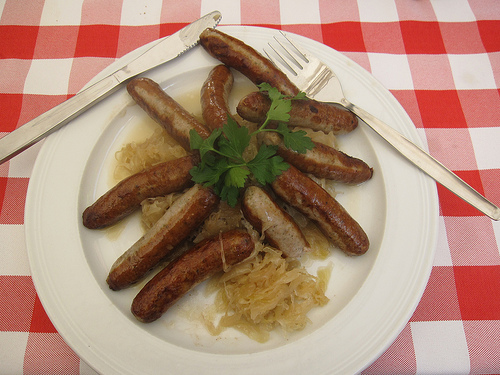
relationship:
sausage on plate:
[128, 228, 255, 323] [23, 24, 439, 374]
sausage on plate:
[107, 181, 221, 292] [23, 24, 439, 374]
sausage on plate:
[82, 154, 198, 231] [23, 24, 439, 374]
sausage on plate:
[127, 75, 209, 152] [23, 24, 439, 374]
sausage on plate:
[200, 64, 239, 129] [23, 24, 439, 374]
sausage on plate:
[199, 28, 302, 98] [23, 24, 439, 374]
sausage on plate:
[237, 93, 359, 132] [23, 24, 439, 374]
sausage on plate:
[257, 128, 374, 185] [23, 24, 439, 374]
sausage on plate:
[273, 164, 371, 256] [23, 24, 439, 374]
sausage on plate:
[241, 185, 312, 263] [23, 24, 439, 374]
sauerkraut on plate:
[110, 127, 332, 342] [23, 24, 439, 374]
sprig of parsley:
[227, 148, 290, 186] [187, 83, 310, 209]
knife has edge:
[0, 10, 221, 164] [179, 15, 222, 58]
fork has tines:
[262, 31, 499, 220] [264, 29, 311, 77]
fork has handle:
[262, 31, 499, 220] [345, 103, 499, 221]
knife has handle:
[0, 10, 221, 164] [0, 79, 111, 167]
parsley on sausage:
[187, 83, 310, 209] [257, 128, 374, 185]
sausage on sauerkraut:
[82, 154, 198, 231] [110, 127, 332, 342]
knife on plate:
[0, 10, 221, 164] [23, 24, 439, 374]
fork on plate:
[262, 31, 499, 220] [23, 24, 439, 374]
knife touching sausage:
[0, 10, 221, 164] [127, 75, 209, 152]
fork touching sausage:
[262, 31, 499, 220] [199, 28, 302, 98]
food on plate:
[79, 29, 374, 346] [23, 24, 439, 374]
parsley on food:
[187, 83, 310, 209] [79, 29, 374, 346]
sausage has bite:
[241, 185, 312, 263] [290, 240, 309, 263]